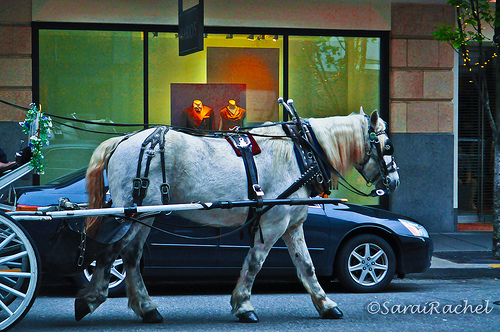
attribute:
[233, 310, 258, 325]
hoof — black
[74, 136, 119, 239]
horse tail — brown, white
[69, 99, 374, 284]
horse — white, brown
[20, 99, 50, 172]
flowers — blue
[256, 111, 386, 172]
mane — white 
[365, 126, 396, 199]
horse bridle — black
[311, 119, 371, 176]
mane — white, brown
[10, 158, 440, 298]
car — parked, shiny, black 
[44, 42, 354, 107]
wall — green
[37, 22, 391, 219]
window — glass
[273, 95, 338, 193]
harness — black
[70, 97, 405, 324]
horse — white 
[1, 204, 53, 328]
carriage wheel — black, white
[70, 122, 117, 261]
tail — bushy, thick, white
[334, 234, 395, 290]
wheel — round